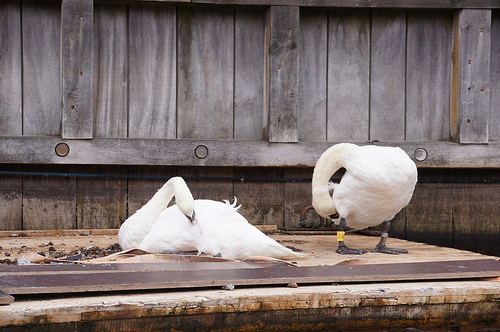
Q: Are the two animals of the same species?
A: Yes, all the animals are swans.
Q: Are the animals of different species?
A: No, all the animals are swans.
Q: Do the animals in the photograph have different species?
A: No, all the animals are swans.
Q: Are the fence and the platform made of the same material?
A: Yes, both the fence and the platform are made of wood.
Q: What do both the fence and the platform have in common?
A: The material, both the fence and the platform are wooden.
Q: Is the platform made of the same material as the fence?
A: Yes, both the platform and the fence are made of wood.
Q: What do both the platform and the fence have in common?
A: The material, both the platform and the fence are wooden.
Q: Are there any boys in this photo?
A: No, there are no boys.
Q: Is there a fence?
A: Yes, there is a fence.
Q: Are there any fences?
A: Yes, there is a fence.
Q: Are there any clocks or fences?
A: Yes, there is a fence.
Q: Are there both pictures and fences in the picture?
A: No, there is a fence but no pictures.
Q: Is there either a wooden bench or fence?
A: Yes, there is a wood fence.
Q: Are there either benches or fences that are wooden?
A: Yes, the fence is wooden.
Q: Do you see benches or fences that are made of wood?
A: Yes, the fence is made of wood.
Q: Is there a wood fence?
A: Yes, there is a wood fence.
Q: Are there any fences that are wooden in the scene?
A: Yes, there is a wood fence.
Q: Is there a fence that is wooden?
A: Yes, there is a fence that is wooden.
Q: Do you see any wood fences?
A: Yes, there is a fence that is made of wood.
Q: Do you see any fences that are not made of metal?
A: Yes, there is a fence that is made of wood.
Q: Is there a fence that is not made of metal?
A: Yes, there is a fence that is made of wood.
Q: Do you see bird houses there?
A: No, there are no bird houses.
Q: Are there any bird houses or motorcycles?
A: No, there are no bird houses or motorcycles.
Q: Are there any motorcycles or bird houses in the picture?
A: No, there are no bird houses or motorcycles.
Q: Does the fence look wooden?
A: Yes, the fence is wooden.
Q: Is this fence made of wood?
A: Yes, the fence is made of wood.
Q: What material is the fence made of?
A: The fence is made of wood.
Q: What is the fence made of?
A: The fence is made of wood.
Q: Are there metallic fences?
A: No, there is a fence but it is wooden.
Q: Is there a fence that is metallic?
A: No, there is a fence but it is wooden.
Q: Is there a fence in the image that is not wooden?
A: No, there is a fence but it is wooden.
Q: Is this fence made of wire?
A: No, the fence is made of wood.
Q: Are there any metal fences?
A: No, there is a fence but it is made of wood.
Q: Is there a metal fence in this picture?
A: No, there is a fence but it is made of wood.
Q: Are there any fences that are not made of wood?
A: No, there is a fence but it is made of wood.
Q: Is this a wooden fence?
A: Yes, this is a wooden fence.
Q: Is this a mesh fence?
A: No, this is a wooden fence.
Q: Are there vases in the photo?
A: No, there are no vases.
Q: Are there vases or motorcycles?
A: No, there are no vases or motorcycles.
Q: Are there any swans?
A: Yes, there is a swan.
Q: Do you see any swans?
A: Yes, there is a swan.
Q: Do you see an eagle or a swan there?
A: Yes, there is a swan.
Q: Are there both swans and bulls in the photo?
A: No, there is a swan but no bulls.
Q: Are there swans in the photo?
A: Yes, there is a swan.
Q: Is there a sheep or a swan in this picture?
A: Yes, there is a swan.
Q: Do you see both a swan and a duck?
A: No, there is a swan but no ducks.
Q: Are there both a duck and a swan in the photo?
A: No, there is a swan but no ducks.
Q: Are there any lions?
A: No, there are no lions.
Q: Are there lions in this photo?
A: No, there are no lions.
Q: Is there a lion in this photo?
A: No, there are no lions.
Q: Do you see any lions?
A: No, there are no lions.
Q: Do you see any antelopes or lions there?
A: No, there are no lions or antelopes.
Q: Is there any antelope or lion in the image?
A: No, there are no lions or antelopes.